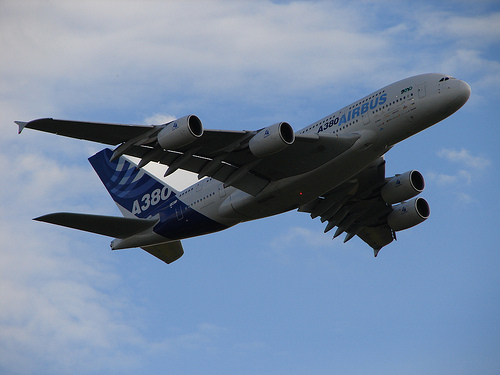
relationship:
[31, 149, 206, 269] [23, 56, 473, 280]
edge of a plane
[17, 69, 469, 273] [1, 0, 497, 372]
airliner in blue sky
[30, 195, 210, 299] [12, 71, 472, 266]
tail of airliner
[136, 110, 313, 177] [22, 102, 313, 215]
engine under wing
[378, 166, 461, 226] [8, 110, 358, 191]
engine under wing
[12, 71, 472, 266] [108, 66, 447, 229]
airliner written on side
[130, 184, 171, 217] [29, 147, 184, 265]
a380 written on tail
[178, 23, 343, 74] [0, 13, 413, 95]
clouds in sky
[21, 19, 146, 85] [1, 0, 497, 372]
white clouds in blue sky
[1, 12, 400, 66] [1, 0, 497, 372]
clouds in blue sky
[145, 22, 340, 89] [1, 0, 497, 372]
clouds in blue sky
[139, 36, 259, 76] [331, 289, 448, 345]
clouds in sky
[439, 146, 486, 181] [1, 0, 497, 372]
clouds in blue sky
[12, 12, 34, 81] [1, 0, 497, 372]
clouds in blue sky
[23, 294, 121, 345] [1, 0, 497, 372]
clouds in blue sky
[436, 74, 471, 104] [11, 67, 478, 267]
nose on plane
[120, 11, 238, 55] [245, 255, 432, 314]
clouds in sky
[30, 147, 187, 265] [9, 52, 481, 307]
tail on plane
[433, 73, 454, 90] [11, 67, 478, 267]
windows on front of plane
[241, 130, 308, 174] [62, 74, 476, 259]
engine on plane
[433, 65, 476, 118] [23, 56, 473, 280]
tip of plane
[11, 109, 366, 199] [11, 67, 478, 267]
wing of plane